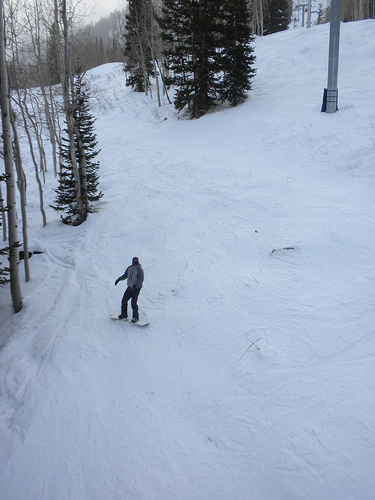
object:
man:
[115, 256, 145, 323]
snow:
[3, 88, 374, 499]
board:
[108, 313, 150, 326]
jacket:
[120, 265, 144, 289]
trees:
[48, 40, 104, 227]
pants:
[121, 286, 141, 318]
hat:
[132, 257, 141, 266]